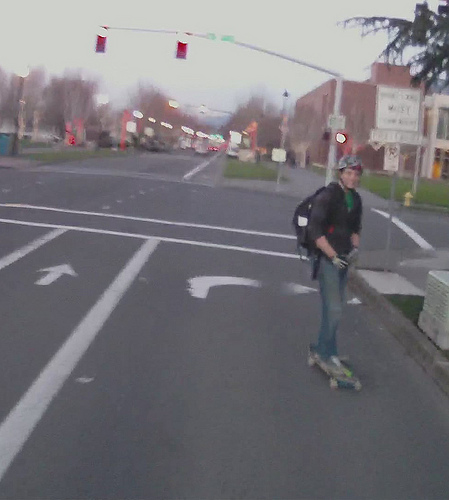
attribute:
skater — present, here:
[262, 148, 383, 406]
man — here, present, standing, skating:
[298, 147, 361, 349]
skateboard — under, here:
[279, 326, 371, 431]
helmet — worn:
[324, 139, 375, 175]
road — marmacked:
[53, 72, 198, 404]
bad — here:
[283, 176, 326, 267]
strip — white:
[5, 220, 152, 460]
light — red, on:
[167, 34, 196, 52]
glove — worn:
[324, 251, 354, 266]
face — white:
[334, 167, 382, 232]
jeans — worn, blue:
[297, 260, 360, 355]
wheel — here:
[324, 377, 342, 400]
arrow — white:
[31, 254, 89, 304]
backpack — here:
[286, 170, 331, 262]